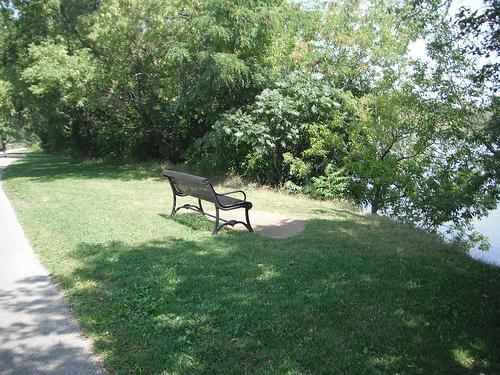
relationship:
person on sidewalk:
[0, 136, 13, 146] [7, 248, 35, 260]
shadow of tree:
[109, 161, 139, 174] [66, 72, 85, 98]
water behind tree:
[483, 219, 497, 230] [435, 165, 461, 203]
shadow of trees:
[109, 161, 139, 174] [164, 72, 201, 114]